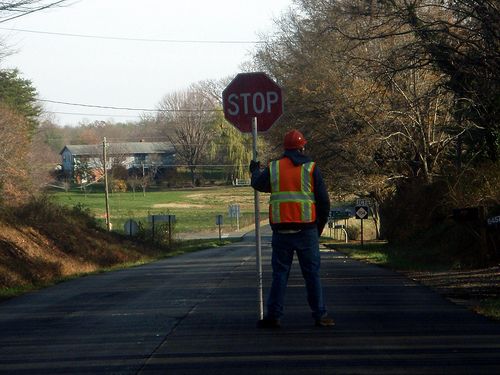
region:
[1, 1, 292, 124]
pale blue of daytime sky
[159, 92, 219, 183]
tree with no leaves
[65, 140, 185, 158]
slanted roof of building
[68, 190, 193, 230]
grass on surface of field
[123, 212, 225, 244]
backs of three signs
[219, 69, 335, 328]
man holding stop sign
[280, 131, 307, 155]
red hard hat on head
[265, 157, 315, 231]
orange vest with silver stripes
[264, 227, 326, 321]
blue jeans on legs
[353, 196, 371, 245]
sign on top of pole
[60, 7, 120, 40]
white clouds in blue sky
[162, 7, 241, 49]
white clouds in blue sky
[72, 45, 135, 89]
white clouds in blue sky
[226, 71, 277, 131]
red and white stop sign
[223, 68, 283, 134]
red and white sign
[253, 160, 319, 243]
person wearing safety vest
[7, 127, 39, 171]
green and brown leaves on tree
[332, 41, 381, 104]
green and brown leaves on tree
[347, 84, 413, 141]
green and brown leaves on tree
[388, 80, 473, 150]
green and brown leaves on tree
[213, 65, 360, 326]
a man holding a stop sign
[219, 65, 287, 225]
a stop sign on a pole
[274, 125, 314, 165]
the head of a person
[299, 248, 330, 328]
a leg of a person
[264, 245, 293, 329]
a leg of a person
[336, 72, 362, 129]
the leaves of a tree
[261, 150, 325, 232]
an orange, yellow, and silver safety pin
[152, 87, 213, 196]
a tree in a yard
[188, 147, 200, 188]
the trunk of a tree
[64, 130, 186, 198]
a house in the distance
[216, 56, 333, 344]
Construction worker holding stop sign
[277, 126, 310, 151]
Red hard hat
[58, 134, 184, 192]
Large gray house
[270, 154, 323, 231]
Bright orange and yellow neon vest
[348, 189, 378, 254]
JCT 104 road sign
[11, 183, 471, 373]
Paved gray road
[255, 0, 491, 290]
Large tree with leaves turning orange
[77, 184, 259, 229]
Yard with grass and dirt areas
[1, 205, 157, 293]
Dried grass hill area beside road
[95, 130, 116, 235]
Wooden telephone pole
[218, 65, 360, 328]
Individual holding a stop sign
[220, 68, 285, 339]
Stop sign is red with silver pole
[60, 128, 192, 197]
Blue house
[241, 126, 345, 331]
Worker wearing red safety hat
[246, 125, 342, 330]
Worker is wearing orange and yellow safety vest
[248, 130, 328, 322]
Blue jeans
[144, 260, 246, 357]
Gray street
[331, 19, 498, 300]
Brown trees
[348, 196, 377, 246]
Black and white sign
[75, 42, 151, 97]
Clear sunny day